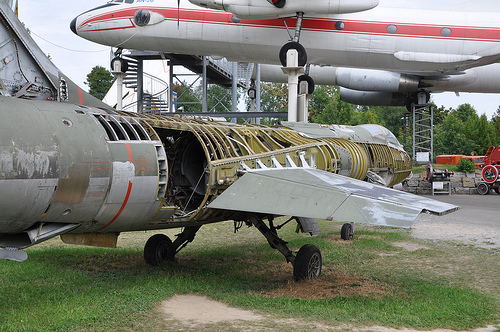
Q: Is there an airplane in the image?
A: Yes, there is an airplane.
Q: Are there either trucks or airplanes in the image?
A: Yes, there is an airplane.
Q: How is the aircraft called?
A: The aircraft is an airplane.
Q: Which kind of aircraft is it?
A: The aircraft is an airplane.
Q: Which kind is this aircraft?
A: This is an airplane.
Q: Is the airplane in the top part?
A: Yes, the airplane is in the top of the image.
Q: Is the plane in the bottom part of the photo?
A: No, the plane is in the top of the image.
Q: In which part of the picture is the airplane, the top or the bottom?
A: The airplane is in the top of the image.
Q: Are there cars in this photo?
A: No, there are no cars.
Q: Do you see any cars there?
A: No, there are no cars.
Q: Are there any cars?
A: No, there are no cars.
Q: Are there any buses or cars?
A: No, there are no cars or buses.